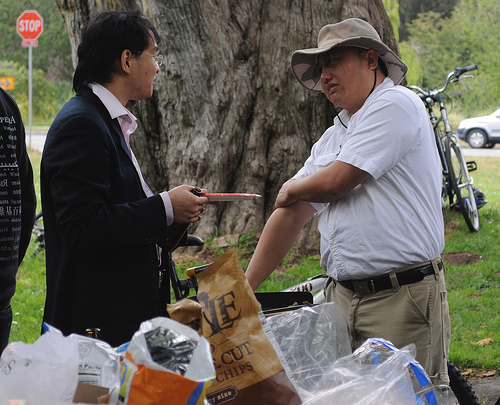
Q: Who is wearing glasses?
A: The man on the left.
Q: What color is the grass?
A: Green.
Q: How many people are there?
A: Two.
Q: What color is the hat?
A: Tan.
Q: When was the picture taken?
A: Daytime.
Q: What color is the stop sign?
A: Red and white.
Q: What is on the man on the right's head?
A: A hat.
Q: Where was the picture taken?
A: In a park.